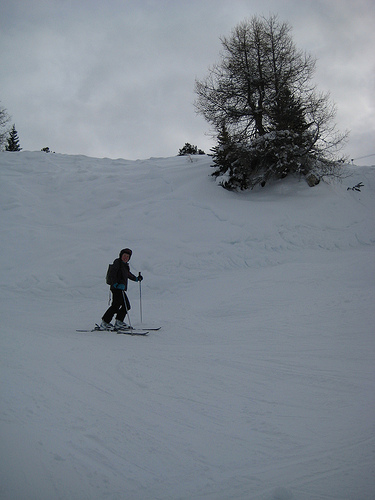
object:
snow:
[0, 150, 375, 500]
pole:
[137, 271, 144, 323]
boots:
[98, 319, 114, 331]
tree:
[194, 14, 353, 193]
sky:
[0, 0, 374, 165]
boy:
[99, 248, 143, 329]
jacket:
[106, 258, 139, 292]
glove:
[136, 274, 145, 282]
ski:
[78, 327, 150, 335]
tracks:
[250, 453, 374, 498]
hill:
[0, 150, 375, 499]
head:
[118, 248, 132, 263]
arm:
[128, 271, 137, 283]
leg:
[115, 290, 131, 323]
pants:
[102, 289, 131, 323]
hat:
[119, 248, 133, 260]